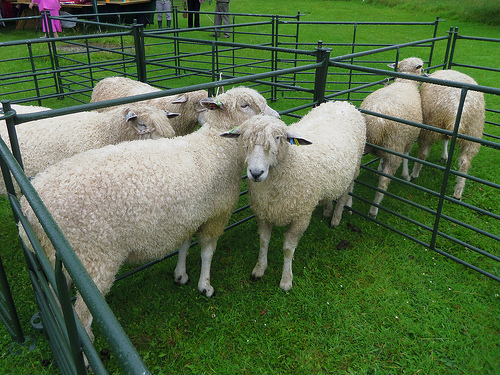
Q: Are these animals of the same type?
A: Yes, all the animals are sheep.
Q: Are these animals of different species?
A: No, all the animals are sheep.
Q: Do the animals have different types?
A: No, all the animals are sheep.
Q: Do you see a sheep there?
A: Yes, there is a sheep.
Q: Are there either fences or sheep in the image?
A: Yes, there is a sheep.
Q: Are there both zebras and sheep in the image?
A: No, there is a sheep but no zebras.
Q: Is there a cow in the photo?
A: No, there are no cows.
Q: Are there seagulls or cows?
A: No, there are no cows or seagulls.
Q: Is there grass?
A: Yes, there is grass.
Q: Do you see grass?
A: Yes, there is grass.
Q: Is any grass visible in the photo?
A: Yes, there is grass.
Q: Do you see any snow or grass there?
A: Yes, there is grass.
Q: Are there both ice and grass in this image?
A: No, there is grass but no ice.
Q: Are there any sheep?
A: Yes, there is a sheep.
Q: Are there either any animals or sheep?
A: Yes, there is a sheep.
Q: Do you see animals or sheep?
A: Yes, there is a sheep.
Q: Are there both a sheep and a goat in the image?
A: No, there is a sheep but no goats.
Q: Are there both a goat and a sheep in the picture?
A: No, there is a sheep but no goats.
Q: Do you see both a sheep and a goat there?
A: No, there is a sheep but no goats.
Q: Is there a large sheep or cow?
A: Yes, there is a large sheep.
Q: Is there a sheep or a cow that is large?
A: Yes, the sheep is large.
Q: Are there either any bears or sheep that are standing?
A: Yes, the sheep is standing.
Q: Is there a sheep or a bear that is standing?
A: Yes, the sheep is standing.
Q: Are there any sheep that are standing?
A: Yes, there is a sheep that is standing.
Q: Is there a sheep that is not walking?
A: Yes, there is a sheep that is standing.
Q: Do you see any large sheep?
A: Yes, there is a large sheep.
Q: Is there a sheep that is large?
A: Yes, there is a sheep that is large.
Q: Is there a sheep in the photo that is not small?
A: Yes, there is a large sheep.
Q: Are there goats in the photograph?
A: No, there are no goats.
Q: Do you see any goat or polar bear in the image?
A: No, there are no goats or polar bears.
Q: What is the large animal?
A: The animal is a sheep.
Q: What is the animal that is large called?
A: The animal is a sheep.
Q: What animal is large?
A: The animal is a sheep.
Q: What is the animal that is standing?
A: The animal is a sheep.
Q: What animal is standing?
A: The animal is a sheep.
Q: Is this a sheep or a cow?
A: This is a sheep.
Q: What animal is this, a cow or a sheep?
A: This is a sheep.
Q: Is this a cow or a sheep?
A: This is a sheep.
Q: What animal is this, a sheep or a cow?
A: This is a sheep.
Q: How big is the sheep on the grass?
A: The sheep is large.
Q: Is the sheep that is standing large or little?
A: The sheep is large.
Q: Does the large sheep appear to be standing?
A: Yes, the sheep is standing.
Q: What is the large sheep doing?
A: The sheep is standing.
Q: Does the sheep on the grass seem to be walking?
A: No, the sheep is standing.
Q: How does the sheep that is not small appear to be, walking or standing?
A: The sheep is standing.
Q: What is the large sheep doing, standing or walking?
A: The sheep is standing.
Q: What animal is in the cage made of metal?
A: The sheep is in the cage.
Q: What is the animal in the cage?
A: The animal is a sheep.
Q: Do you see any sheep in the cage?
A: Yes, there is a sheep in the cage.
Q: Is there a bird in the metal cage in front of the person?
A: No, there is a sheep in the cage.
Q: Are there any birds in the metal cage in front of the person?
A: No, there is a sheep in the cage.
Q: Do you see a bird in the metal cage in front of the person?
A: No, there is a sheep in the cage.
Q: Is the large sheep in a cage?
A: Yes, the sheep is in a cage.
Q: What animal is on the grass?
A: The sheep is on the grass.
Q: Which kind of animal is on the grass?
A: The animal is a sheep.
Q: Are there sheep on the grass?
A: Yes, there is a sheep on the grass.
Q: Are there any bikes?
A: No, there are no bikes.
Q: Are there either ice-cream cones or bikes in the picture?
A: No, there are no bikes or ice-cream cones.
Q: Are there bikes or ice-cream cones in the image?
A: No, there are no bikes or ice-cream cones.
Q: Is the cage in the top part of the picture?
A: Yes, the cage is in the top of the image.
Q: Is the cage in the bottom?
A: No, the cage is in the top of the image.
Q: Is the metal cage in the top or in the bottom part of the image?
A: The cage is in the top of the image.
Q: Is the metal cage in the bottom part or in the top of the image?
A: The cage is in the top of the image.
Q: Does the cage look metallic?
A: Yes, the cage is metallic.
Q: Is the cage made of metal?
A: Yes, the cage is made of metal.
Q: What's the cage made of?
A: The cage is made of metal.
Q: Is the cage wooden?
A: No, the cage is metallic.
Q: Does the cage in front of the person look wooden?
A: No, the cage is metallic.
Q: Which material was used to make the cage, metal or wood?
A: The cage is made of metal.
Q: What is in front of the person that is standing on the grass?
A: The cage is in front of the person.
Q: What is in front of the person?
A: The cage is in front of the person.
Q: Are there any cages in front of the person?
A: Yes, there is a cage in front of the person.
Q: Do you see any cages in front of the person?
A: Yes, there is a cage in front of the person.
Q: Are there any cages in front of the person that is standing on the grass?
A: Yes, there is a cage in front of the person.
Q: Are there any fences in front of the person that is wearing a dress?
A: No, there is a cage in front of the person.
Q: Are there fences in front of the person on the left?
A: No, there is a cage in front of the person.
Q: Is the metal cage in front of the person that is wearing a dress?
A: Yes, the cage is in front of the person.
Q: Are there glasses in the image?
A: No, there are no glasses.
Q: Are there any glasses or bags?
A: No, there are no glasses or bags.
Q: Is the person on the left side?
A: Yes, the person is on the left of the image.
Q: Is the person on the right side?
A: No, the person is on the left of the image.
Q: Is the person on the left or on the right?
A: The person is on the left of the image.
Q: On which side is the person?
A: The person is on the left of the image.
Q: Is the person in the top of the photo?
A: Yes, the person is in the top of the image.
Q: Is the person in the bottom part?
A: No, the person is in the top of the image.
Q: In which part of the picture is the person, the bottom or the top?
A: The person is in the top of the image.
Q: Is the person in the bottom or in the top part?
A: The person is in the top of the image.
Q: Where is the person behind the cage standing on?
A: The person is standing on the grass.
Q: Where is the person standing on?
A: The person is standing on the grass.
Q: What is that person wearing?
A: The person is wearing a dress.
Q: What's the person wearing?
A: The person is wearing a dress.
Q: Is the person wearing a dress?
A: Yes, the person is wearing a dress.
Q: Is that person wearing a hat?
A: No, the person is wearing a dress.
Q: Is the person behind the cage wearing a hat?
A: No, the person is wearing a dress.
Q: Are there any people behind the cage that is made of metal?
A: Yes, there is a person behind the cage.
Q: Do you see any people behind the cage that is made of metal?
A: Yes, there is a person behind the cage.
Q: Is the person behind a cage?
A: Yes, the person is behind a cage.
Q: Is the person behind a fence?
A: No, the person is behind a cage.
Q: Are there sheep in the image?
A: Yes, there is a sheep.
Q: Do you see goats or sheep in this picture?
A: Yes, there is a sheep.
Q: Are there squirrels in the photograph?
A: No, there are no squirrels.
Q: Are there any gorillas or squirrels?
A: No, there are no squirrels or gorillas.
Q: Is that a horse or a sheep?
A: That is a sheep.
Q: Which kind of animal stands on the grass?
A: The animal is a sheep.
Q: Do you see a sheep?
A: Yes, there is a sheep.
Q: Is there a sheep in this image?
A: Yes, there is a sheep.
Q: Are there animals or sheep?
A: Yes, there is a sheep.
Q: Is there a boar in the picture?
A: No, there are no boars.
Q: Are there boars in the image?
A: No, there are no boars.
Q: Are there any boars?
A: No, there are no boars.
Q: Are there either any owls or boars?
A: No, there are no boars or owls.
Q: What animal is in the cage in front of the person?
A: The sheep is in the cage.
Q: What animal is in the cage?
A: The sheep is in the cage.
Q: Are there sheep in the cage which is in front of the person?
A: Yes, there is a sheep in the cage.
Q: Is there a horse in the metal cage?
A: No, there is a sheep in the cage.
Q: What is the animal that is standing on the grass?
A: The animal is a sheep.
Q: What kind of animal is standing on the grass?
A: The animal is a sheep.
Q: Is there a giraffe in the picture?
A: No, there are no giraffes.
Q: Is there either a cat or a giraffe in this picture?
A: No, there are no giraffes or cats.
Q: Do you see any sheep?
A: Yes, there is a sheep.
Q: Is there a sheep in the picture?
A: Yes, there is a sheep.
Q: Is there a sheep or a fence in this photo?
A: Yes, there is a sheep.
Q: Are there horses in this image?
A: No, there are no horses.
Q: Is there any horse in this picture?
A: No, there are no horses.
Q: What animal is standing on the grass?
A: The animal is a sheep.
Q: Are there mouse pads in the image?
A: No, there are no mouse pads.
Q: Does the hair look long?
A: Yes, the hair is long.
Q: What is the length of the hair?
A: The hair is long.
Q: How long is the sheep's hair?
A: The hair is long.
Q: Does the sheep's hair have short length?
A: No, the hair is long.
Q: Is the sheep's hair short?
A: No, the hair is long.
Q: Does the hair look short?
A: No, the hair is long.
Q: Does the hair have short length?
A: No, the hair is long.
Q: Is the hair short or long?
A: The hair is long.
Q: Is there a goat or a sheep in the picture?
A: Yes, there is a sheep.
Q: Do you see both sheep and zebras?
A: No, there is a sheep but no zebras.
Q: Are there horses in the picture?
A: No, there are no horses.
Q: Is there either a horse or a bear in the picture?
A: No, there are no horses or bears.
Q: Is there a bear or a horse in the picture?
A: No, there are no horses or bears.